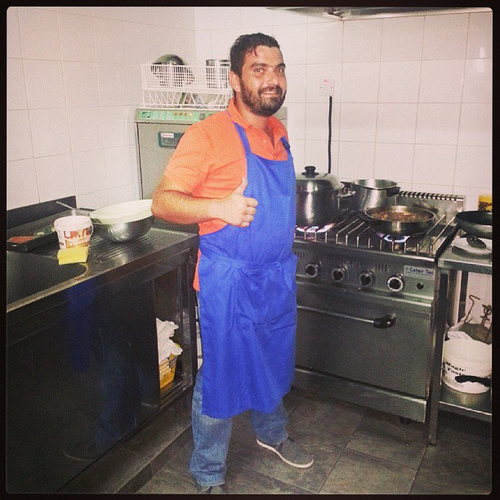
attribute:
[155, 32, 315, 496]
man — cooking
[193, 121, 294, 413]
apron — blue, long, bright blue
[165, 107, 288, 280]
shirt — orange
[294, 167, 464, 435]
stove — large, stainless steel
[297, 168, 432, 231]
food — cooking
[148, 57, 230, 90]
bowls — aluminum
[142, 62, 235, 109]
rack — white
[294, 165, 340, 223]
pot — covered, lidded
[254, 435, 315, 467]
sneakers — grey, black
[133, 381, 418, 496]
floor — stone, gray, grey, ceramic, tiled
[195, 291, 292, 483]
jeans — light blue, blue, denim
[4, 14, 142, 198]
tile — white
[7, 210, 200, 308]
sink — large, stainless steel